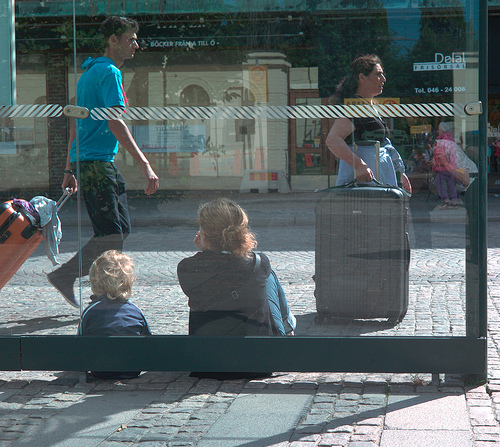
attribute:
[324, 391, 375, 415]
street — brick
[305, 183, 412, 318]
suitcase — orange, black, large, section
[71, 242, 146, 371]
child — sitting, small, blonde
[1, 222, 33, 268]
luggage — orange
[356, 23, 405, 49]
window — arched, edge, glass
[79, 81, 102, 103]
shirt — blue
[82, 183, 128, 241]
pants — black, jeans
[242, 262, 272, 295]
jacket — part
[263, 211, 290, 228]
walkpath — part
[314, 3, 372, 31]
glass — part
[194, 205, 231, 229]
hair — blonde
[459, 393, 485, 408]
edge — part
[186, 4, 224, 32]
shade — part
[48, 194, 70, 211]
handle — part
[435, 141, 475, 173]
bag — part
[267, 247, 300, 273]
ground — paved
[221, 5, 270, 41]
partition — glass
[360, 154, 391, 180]
skirt — blue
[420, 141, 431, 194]
person — bending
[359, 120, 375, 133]
top — black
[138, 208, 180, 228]
surface — rocky